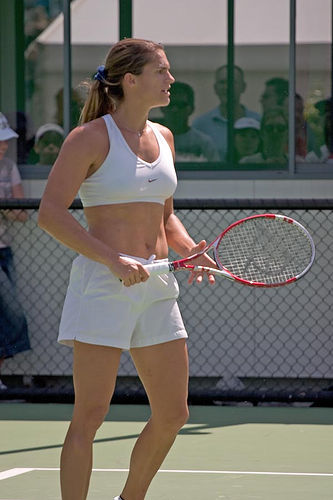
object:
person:
[35, 36, 221, 499]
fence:
[0, 195, 333, 403]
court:
[0, 398, 333, 500]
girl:
[38, 37, 218, 498]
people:
[0, 107, 31, 389]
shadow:
[0, 403, 332, 456]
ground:
[233, 129, 261, 155]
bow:
[92, 64, 105, 82]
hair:
[75, 37, 162, 126]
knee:
[150, 398, 189, 432]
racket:
[119, 214, 316, 289]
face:
[140, 48, 175, 106]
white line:
[186, 470, 333, 476]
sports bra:
[77, 114, 180, 208]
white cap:
[233, 116, 260, 130]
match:
[0, 37, 333, 499]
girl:
[233, 116, 264, 164]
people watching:
[191, 64, 262, 162]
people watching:
[258, 77, 289, 112]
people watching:
[148, 81, 221, 162]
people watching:
[28, 122, 65, 166]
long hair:
[78, 65, 118, 126]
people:
[238, 104, 304, 165]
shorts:
[56, 253, 188, 351]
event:
[0, 42, 333, 499]